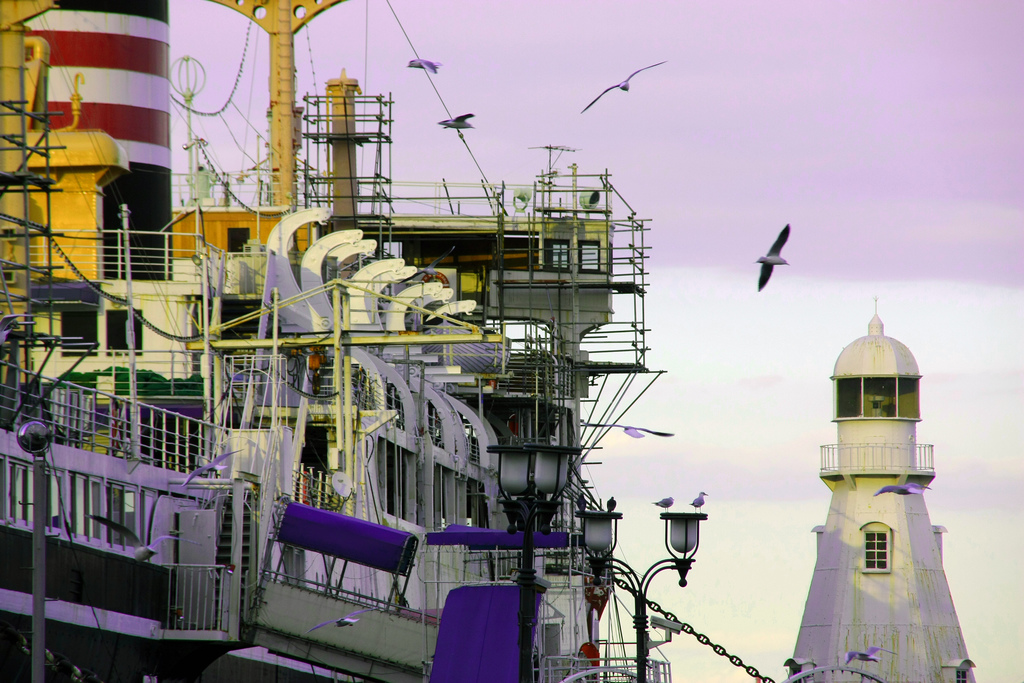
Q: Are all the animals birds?
A: No, there are both seagulls and birds.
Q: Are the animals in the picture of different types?
A: Yes, they are seagulls and birds.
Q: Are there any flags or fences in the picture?
A: No, there are no fences or flags.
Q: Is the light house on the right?
A: Yes, the light house is on the right of the image.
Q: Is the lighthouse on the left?
A: No, the lighthouse is on the right of the image.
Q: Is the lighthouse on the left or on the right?
A: The lighthouse is on the right of the image.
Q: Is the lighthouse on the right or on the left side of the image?
A: The lighthouse is on the right of the image.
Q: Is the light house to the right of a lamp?
A: Yes, the light house is to the right of a lamp.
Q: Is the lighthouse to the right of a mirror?
A: No, the lighthouse is to the right of a lamp.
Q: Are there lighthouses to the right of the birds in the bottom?
A: Yes, there is a lighthouse to the right of the birds.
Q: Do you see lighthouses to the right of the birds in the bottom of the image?
A: Yes, there is a lighthouse to the right of the birds.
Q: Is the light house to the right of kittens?
A: No, the light house is to the right of the birds.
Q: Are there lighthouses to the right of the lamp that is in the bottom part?
A: Yes, there is a lighthouse to the right of the lamp.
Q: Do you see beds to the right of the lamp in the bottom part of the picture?
A: No, there is a lighthouse to the right of the lamp.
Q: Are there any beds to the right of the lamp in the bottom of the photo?
A: No, there is a lighthouse to the right of the lamp.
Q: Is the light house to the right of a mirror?
A: No, the light house is to the right of a lamp.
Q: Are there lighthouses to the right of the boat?
A: Yes, there is a lighthouse to the right of the boat.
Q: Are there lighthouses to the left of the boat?
A: No, the lighthouse is to the right of the boat.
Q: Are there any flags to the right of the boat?
A: No, there is a lighthouse to the right of the boat.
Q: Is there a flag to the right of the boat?
A: No, there is a lighthouse to the right of the boat.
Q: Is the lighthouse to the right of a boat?
A: Yes, the lighthouse is to the right of a boat.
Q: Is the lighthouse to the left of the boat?
A: No, the lighthouse is to the right of the boat.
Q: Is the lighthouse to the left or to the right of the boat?
A: The lighthouse is to the right of the boat.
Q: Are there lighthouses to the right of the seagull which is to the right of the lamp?
A: Yes, there is a lighthouse to the right of the sea gull.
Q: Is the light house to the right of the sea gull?
A: Yes, the light house is to the right of the sea gull.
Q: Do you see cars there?
A: No, there are no cars.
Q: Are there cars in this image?
A: No, there are no cars.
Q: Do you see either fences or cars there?
A: No, there are no cars or fences.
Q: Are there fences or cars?
A: No, there are no cars or fences.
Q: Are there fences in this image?
A: No, there are no fences.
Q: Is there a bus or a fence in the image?
A: No, there are no fences or buses.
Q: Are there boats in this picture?
A: Yes, there is a boat.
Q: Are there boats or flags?
A: Yes, there is a boat.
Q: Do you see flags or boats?
A: Yes, there is a boat.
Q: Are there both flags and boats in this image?
A: No, there is a boat but no flags.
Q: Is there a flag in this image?
A: No, there are no flags.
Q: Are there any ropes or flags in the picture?
A: No, there are no flags or ropes.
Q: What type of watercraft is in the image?
A: The watercraft is a boat.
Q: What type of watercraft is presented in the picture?
A: The watercraft is a boat.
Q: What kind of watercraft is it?
A: The watercraft is a boat.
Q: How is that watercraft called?
A: This is a boat.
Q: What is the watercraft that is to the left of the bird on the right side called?
A: The watercraft is a boat.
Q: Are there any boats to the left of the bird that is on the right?
A: Yes, there is a boat to the left of the bird.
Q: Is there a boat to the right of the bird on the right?
A: No, the boat is to the left of the bird.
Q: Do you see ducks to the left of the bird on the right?
A: No, there is a boat to the left of the bird.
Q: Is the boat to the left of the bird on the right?
A: Yes, the boat is to the left of the bird.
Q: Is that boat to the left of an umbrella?
A: No, the boat is to the left of the bird.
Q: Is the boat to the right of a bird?
A: No, the boat is to the left of a bird.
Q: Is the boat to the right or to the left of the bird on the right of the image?
A: The boat is to the left of the bird.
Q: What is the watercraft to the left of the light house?
A: The watercraft is a boat.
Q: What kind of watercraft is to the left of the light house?
A: The watercraft is a boat.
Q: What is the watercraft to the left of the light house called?
A: The watercraft is a boat.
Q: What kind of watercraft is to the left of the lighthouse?
A: The watercraft is a boat.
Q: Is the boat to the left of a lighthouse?
A: Yes, the boat is to the left of a lighthouse.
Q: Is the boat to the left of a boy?
A: No, the boat is to the left of a lighthouse.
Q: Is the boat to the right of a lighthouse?
A: No, the boat is to the left of a lighthouse.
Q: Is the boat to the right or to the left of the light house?
A: The boat is to the left of the light house.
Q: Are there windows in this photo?
A: Yes, there is a window.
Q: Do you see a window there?
A: Yes, there is a window.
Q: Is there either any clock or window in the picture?
A: Yes, there is a window.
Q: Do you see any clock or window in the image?
A: Yes, there is a window.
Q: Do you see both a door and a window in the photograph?
A: No, there is a window but no doors.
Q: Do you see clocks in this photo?
A: No, there are no clocks.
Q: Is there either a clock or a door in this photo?
A: No, there are no clocks or doors.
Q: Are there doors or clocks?
A: No, there are no clocks or doors.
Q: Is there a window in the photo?
A: Yes, there is a window.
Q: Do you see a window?
A: Yes, there is a window.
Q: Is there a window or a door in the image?
A: Yes, there is a window.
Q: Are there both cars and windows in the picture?
A: No, there is a window but no cars.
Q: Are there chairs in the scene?
A: No, there are no chairs.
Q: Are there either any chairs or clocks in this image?
A: No, there are no chairs or clocks.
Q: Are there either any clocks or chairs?
A: No, there are no chairs or clocks.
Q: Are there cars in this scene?
A: No, there are no cars.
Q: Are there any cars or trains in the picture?
A: No, there are no cars or trains.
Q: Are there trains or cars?
A: No, there are no cars or trains.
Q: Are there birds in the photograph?
A: Yes, there are birds.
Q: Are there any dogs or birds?
A: Yes, there are birds.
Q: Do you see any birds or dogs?
A: Yes, there are birds.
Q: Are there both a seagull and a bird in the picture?
A: Yes, there are both a bird and a seagull.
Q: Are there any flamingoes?
A: No, there are no flamingoes.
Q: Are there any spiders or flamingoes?
A: No, there are no flamingoes or spiders.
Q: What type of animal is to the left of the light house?
A: The animals are birds.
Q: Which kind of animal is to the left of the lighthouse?
A: The animals are birds.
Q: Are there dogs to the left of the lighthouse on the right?
A: No, there are birds to the left of the lighthouse.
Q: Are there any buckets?
A: No, there are no buckets.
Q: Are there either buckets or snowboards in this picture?
A: No, there are no buckets or snowboards.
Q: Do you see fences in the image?
A: No, there are no fences.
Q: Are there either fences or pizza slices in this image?
A: No, there are no fences or pizza slices.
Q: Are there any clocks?
A: No, there are no clocks.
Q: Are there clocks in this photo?
A: No, there are no clocks.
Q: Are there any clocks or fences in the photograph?
A: No, there are no clocks or fences.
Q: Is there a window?
A: Yes, there is a window.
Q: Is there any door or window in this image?
A: Yes, there is a window.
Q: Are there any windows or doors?
A: Yes, there is a window.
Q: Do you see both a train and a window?
A: No, there is a window but no trains.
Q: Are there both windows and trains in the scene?
A: No, there is a window but no trains.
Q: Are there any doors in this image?
A: No, there are no doors.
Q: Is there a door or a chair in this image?
A: No, there are no doors or chairs.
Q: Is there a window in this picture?
A: Yes, there is a window.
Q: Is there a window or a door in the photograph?
A: Yes, there is a window.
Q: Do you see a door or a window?
A: Yes, there is a window.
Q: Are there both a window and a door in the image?
A: No, there is a window but no doors.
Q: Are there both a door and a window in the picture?
A: No, there is a window but no doors.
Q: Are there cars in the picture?
A: No, there are no cars.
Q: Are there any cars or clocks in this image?
A: No, there are no cars or clocks.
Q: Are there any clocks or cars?
A: No, there are no cars or clocks.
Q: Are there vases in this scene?
A: No, there are no vases.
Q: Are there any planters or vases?
A: No, there are no vases or planters.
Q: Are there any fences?
A: No, there are no fences.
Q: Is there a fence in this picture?
A: No, there are no fences.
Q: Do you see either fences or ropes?
A: No, there are no fences or ropes.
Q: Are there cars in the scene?
A: No, there are no cars.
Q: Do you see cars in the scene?
A: No, there are no cars.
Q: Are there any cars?
A: No, there are no cars.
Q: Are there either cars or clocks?
A: No, there are no cars or clocks.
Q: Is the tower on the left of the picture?
A: Yes, the tower is on the left of the image.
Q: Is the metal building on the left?
A: Yes, the tower is on the left of the image.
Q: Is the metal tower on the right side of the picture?
A: No, the tower is on the left of the image.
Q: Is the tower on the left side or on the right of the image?
A: The tower is on the left of the image.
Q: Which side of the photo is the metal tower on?
A: The tower is on the left of the image.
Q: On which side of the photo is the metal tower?
A: The tower is on the left of the image.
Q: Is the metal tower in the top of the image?
A: Yes, the tower is in the top of the image.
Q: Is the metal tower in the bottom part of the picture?
A: No, the tower is in the top of the image.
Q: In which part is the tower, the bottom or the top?
A: The tower is in the top of the image.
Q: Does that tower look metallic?
A: Yes, the tower is metallic.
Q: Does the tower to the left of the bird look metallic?
A: Yes, the tower is metallic.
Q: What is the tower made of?
A: The tower is made of metal.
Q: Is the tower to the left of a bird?
A: Yes, the tower is to the left of a bird.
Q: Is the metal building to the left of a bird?
A: Yes, the tower is to the left of a bird.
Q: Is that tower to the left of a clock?
A: No, the tower is to the left of a bird.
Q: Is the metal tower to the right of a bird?
A: No, the tower is to the left of a bird.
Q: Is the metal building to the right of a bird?
A: No, the tower is to the left of a bird.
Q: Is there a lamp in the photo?
A: Yes, there is a lamp.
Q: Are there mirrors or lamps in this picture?
A: Yes, there is a lamp.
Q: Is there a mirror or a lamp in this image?
A: Yes, there is a lamp.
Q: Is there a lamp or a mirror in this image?
A: Yes, there is a lamp.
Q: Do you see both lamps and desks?
A: No, there is a lamp but no desks.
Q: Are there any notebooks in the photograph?
A: No, there are no notebooks.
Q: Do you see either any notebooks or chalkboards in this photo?
A: No, there are no notebooks or chalkboards.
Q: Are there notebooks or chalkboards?
A: No, there are no notebooks or chalkboards.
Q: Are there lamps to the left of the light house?
A: Yes, there is a lamp to the left of the light house.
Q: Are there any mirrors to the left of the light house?
A: No, there is a lamp to the left of the light house.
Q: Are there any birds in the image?
A: Yes, there is a bird.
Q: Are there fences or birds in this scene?
A: Yes, there is a bird.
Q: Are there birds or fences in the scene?
A: Yes, there is a bird.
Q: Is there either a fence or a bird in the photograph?
A: Yes, there is a bird.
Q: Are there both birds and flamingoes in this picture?
A: No, there is a bird but no flamingoes.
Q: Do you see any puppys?
A: No, there are no puppys.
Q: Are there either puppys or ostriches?
A: No, there are no puppys or ostriches.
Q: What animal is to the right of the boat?
A: The animal is a bird.